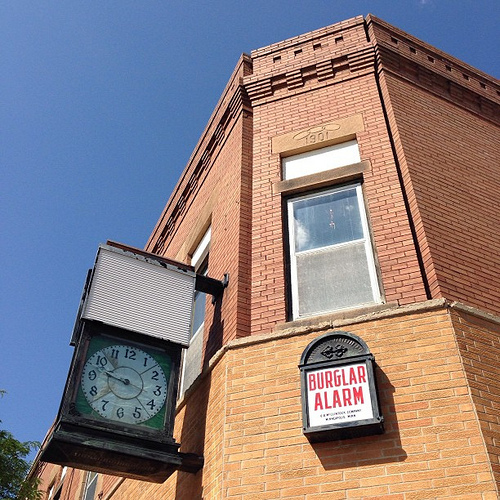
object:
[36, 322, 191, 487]
clock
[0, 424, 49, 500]
tree limbs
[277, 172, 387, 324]
window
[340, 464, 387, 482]
brick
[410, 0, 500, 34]
clouds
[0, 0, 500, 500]
ski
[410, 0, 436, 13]
white clouds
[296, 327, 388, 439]
alarm sign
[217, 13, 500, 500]
wall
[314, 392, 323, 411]
letters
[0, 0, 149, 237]
clouds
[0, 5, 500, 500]
building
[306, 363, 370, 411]
burglar alarm